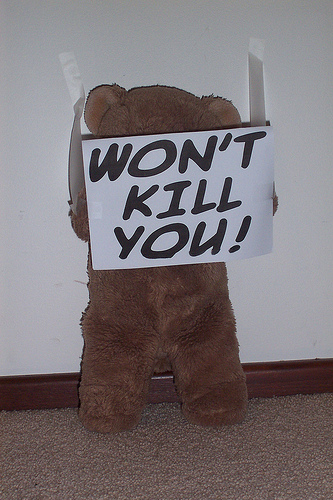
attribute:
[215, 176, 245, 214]
letter — black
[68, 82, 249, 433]
stuffed bear — small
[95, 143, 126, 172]
letter — black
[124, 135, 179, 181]
letter — black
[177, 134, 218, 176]
letter — black